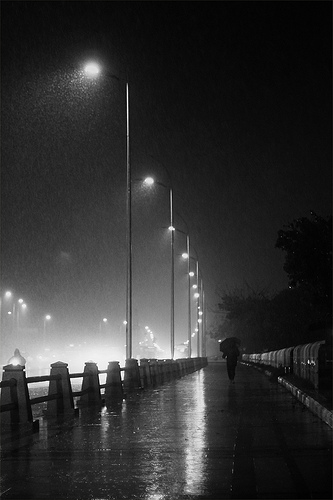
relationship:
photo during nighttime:
[1, 1, 332, 499] [4, 1, 332, 500]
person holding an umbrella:
[221, 348, 243, 378] [220, 334, 253, 357]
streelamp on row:
[80, 59, 136, 406] [74, 57, 209, 397]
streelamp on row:
[142, 173, 178, 370] [74, 57, 209, 397]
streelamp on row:
[165, 218, 197, 367] [74, 57, 209, 397]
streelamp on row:
[184, 260, 205, 367] [74, 57, 209, 397]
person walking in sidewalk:
[221, 348, 243, 378] [0, 351, 331, 500]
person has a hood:
[221, 348, 243, 378] [223, 342, 242, 360]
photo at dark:
[1, 1, 332, 499] [4, 4, 330, 500]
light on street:
[137, 360, 210, 499] [5, 341, 330, 499]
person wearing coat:
[221, 348, 243, 378] [220, 349, 243, 378]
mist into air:
[7, 71, 204, 364] [4, 6, 330, 377]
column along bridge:
[1, 364, 41, 441] [4, 344, 332, 498]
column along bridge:
[41, 359, 80, 424] [4, 344, 332, 498]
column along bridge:
[78, 363, 104, 410] [4, 344, 332, 498]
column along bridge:
[106, 362, 127, 406] [4, 344, 332, 498]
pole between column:
[20, 373, 54, 410] [1, 364, 41, 441]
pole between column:
[69, 369, 91, 409] [41, 359, 80, 424]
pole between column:
[96, 364, 113, 403] [78, 363, 104, 410]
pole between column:
[122, 360, 132, 390] [106, 362, 127, 406]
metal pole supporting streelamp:
[119, 85, 137, 363] [80, 59, 136, 406]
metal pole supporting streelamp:
[165, 189, 180, 357] [142, 173, 178, 370]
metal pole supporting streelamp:
[186, 236, 197, 363] [165, 218, 197, 367]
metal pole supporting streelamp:
[192, 257, 202, 367] [184, 260, 205, 367]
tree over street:
[281, 210, 332, 346] [5, 341, 330, 499]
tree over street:
[221, 285, 295, 350] [5, 341, 330, 499]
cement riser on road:
[227, 337, 330, 387] [0, 351, 331, 500]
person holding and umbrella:
[221, 348, 243, 378] [220, 334, 253, 357]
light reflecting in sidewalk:
[137, 360, 210, 499] [0, 351, 331, 500]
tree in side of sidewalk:
[281, 210, 332, 346] [0, 351, 331, 500]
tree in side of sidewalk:
[221, 285, 295, 350] [0, 351, 331, 500]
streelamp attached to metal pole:
[80, 59, 136, 406] [119, 85, 137, 363]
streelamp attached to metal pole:
[142, 173, 178, 370] [165, 189, 180, 357]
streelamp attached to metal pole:
[165, 218, 197, 367] [186, 236, 197, 363]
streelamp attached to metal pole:
[184, 260, 205, 367] [192, 257, 202, 367]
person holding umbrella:
[221, 348, 243, 378] [220, 334, 253, 357]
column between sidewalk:
[1, 364, 41, 441] [0, 351, 331, 500]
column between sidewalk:
[41, 359, 80, 424] [0, 351, 331, 500]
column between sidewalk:
[78, 363, 104, 410] [0, 351, 331, 500]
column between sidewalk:
[106, 362, 127, 406] [0, 351, 331, 500]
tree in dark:
[281, 210, 332, 346] [4, 4, 330, 500]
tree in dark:
[221, 285, 295, 350] [4, 4, 330, 500]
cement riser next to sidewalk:
[227, 337, 330, 387] [0, 351, 331, 500]